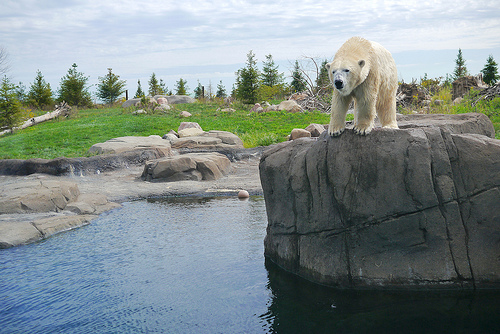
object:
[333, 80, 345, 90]
nose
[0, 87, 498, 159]
grass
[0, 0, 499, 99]
sky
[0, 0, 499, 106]
clouds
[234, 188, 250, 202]
ball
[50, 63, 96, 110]
tree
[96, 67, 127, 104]
tree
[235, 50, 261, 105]
tree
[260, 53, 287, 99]
tree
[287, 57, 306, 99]
tree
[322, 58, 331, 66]
ears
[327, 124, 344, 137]
paws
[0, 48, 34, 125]
trees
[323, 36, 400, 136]
bear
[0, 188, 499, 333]
pond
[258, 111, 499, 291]
rock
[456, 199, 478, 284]
cracks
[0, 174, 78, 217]
rocks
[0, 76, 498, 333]
enclosure